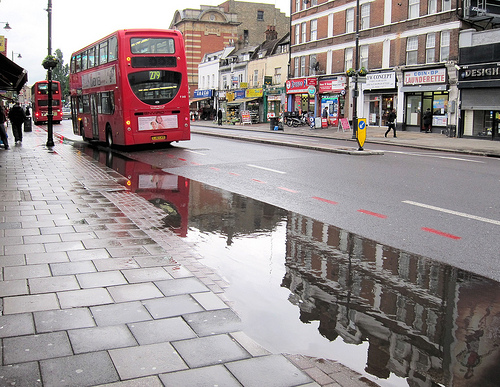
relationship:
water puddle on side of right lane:
[41, 123, 499, 386] [38, 115, 471, 358]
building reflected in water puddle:
[285, 213, 498, 386] [41, 123, 499, 386]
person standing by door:
[424, 107, 433, 134] [419, 94, 434, 135]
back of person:
[10, 100, 27, 149] [9, 97, 28, 148]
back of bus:
[119, 28, 190, 150] [70, 28, 192, 150]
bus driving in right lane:
[70, 28, 192, 150] [38, 118, 499, 358]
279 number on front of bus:
[146, 70, 163, 83] [70, 28, 192, 150]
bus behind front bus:
[30, 79, 64, 126] [70, 28, 192, 150]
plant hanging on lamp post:
[40, 54, 59, 70] [44, 1, 59, 152]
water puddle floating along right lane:
[41, 123, 499, 386] [38, 115, 471, 358]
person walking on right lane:
[9, 97, 28, 148] [38, 115, 471, 358]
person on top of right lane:
[0, 101, 10, 151] [38, 115, 471, 358]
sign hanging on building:
[286, 78, 309, 92] [287, 0, 461, 137]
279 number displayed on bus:
[146, 70, 163, 83] [70, 28, 192, 150]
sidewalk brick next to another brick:
[25, 271, 81, 295] [73, 268, 131, 291]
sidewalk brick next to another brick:
[67, 316, 138, 356] [124, 312, 202, 347]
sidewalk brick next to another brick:
[156, 363, 246, 386] [222, 351, 312, 386]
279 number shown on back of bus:
[146, 70, 163, 83] [70, 28, 192, 150]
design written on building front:
[459, 62, 499, 82] [455, 2, 499, 144]